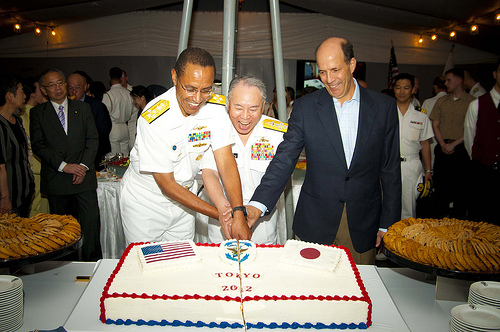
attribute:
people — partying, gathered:
[10, 84, 119, 209]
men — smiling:
[161, 54, 380, 229]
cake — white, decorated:
[121, 246, 362, 323]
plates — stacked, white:
[0, 305, 22, 328]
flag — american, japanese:
[138, 237, 203, 274]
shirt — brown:
[433, 107, 463, 135]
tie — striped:
[54, 103, 70, 124]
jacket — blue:
[295, 120, 328, 218]